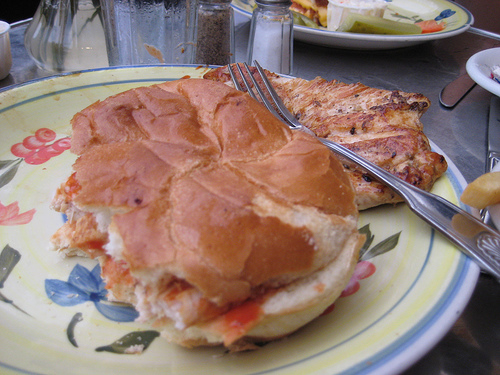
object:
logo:
[473, 232, 498, 263]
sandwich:
[51, 74, 368, 354]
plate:
[466, 46, 499, 98]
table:
[0, 0, 499, 374]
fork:
[226, 57, 498, 277]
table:
[369, 39, 496, 141]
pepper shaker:
[190, 2, 234, 64]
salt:
[250, 18, 287, 69]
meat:
[53, 181, 215, 335]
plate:
[0, 65, 484, 375]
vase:
[29, 1, 121, 90]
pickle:
[319, 7, 430, 34]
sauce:
[204, 296, 281, 345]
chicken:
[201, 60, 448, 211]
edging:
[357, 108, 484, 373]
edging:
[0, 53, 248, 117]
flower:
[45, 258, 139, 321]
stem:
[42, 10, 75, 72]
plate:
[233, 1, 479, 43]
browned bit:
[404, 97, 423, 114]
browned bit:
[434, 152, 444, 169]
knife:
[439, 69, 475, 108]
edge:
[298, 35, 498, 175]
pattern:
[95, 327, 164, 355]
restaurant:
[0, 0, 496, 371]